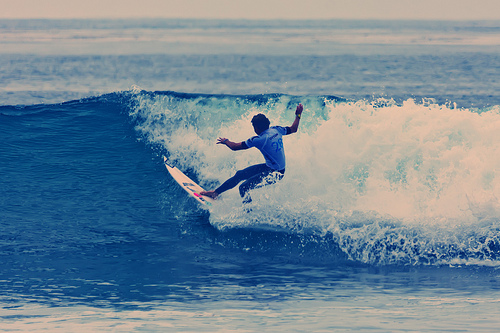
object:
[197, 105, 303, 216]
man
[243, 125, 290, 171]
top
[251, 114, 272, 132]
head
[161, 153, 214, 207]
surfboard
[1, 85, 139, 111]
unbroken wave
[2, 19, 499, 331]
water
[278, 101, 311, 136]
arms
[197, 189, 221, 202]
right foot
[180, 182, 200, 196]
printing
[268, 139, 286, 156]
28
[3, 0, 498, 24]
sky